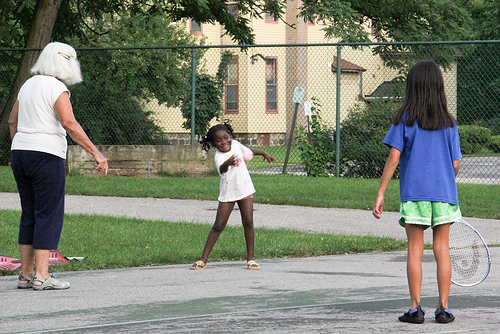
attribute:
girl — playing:
[185, 114, 279, 278]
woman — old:
[10, 31, 111, 290]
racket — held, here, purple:
[438, 173, 498, 316]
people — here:
[13, 17, 478, 330]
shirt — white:
[207, 147, 268, 207]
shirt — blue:
[392, 104, 470, 225]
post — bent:
[279, 38, 309, 185]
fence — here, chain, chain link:
[127, 22, 485, 186]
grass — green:
[46, 225, 174, 267]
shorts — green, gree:
[381, 187, 482, 250]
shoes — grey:
[13, 261, 77, 300]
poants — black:
[4, 139, 77, 271]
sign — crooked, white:
[273, 74, 317, 184]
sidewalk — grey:
[132, 201, 210, 246]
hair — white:
[24, 39, 87, 84]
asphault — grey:
[165, 252, 368, 317]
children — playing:
[172, 35, 473, 330]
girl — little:
[367, 42, 470, 322]